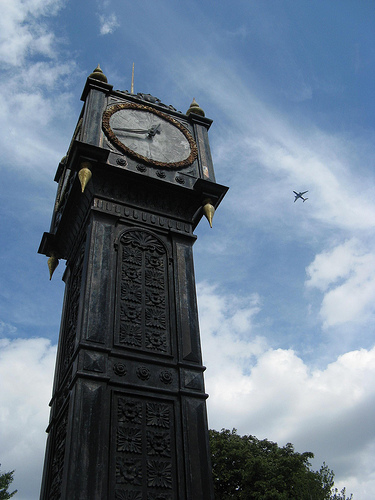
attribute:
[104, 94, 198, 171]
clock face — large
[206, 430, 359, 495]
bushy tree — large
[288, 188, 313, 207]
airplane — distant 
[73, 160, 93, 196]
spike — pointing downward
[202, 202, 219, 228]
ornamental spike — pointing downward, golden 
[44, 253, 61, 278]
ornamental spike — pointing downward, golden 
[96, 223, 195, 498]
ornate designs — Ornate 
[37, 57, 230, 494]
tower — tall, ornate, black, clock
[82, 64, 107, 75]
ornamental spike — golden , pointing upwards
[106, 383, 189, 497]
etched pattern — Etched 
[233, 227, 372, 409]
sky — white 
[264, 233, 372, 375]
white clouds — fluffy 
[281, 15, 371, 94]
blue sky — Blue 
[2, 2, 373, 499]
blue sky — Blue , cloudy 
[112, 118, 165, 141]
black hands — black 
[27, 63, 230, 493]
clock tower — tall , black , iron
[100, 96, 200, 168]
clock face — round 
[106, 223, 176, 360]
pattern — arched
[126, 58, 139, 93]
pole — gold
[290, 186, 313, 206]
plane — high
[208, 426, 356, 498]
tree — healthy, full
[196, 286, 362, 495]
cloud — white, fluffy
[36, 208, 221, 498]
pillar — gray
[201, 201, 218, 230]
decoration — gold, pointy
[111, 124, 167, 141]
hands — black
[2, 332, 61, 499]
cloud — large, gray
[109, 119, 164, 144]
hands — black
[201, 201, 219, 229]
object — pointy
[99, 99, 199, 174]
clock — round, rusted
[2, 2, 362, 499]
sky — hazy, blue, cloudy